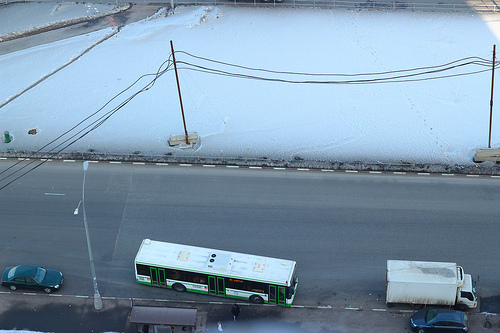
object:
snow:
[0, 8, 497, 156]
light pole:
[72, 160, 104, 311]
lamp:
[73, 208, 78, 215]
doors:
[151, 266, 166, 287]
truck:
[386, 259, 478, 312]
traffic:
[0, 209, 478, 333]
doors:
[208, 276, 226, 297]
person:
[483, 315, 493, 328]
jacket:
[231, 307, 240, 315]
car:
[0, 265, 65, 294]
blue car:
[410, 308, 469, 333]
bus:
[133, 238, 299, 307]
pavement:
[0, 156, 500, 333]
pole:
[86, 242, 99, 292]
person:
[231, 304, 242, 322]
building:
[128, 305, 198, 332]